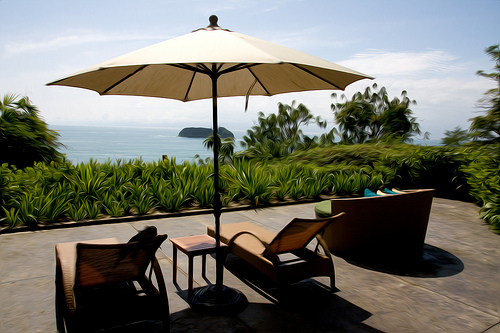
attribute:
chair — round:
[331, 177, 423, 247]